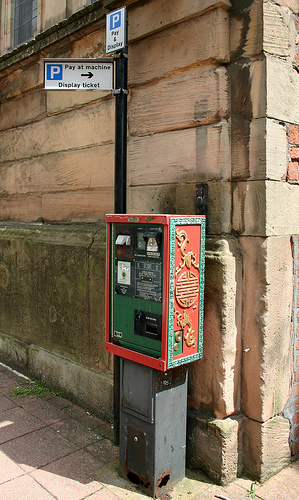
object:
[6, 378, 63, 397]
weeds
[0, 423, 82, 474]
cement tile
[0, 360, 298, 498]
ground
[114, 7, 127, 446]
pole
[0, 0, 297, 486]
building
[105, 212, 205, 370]
box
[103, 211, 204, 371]
machine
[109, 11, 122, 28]
p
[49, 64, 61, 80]
p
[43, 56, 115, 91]
sign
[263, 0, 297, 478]
wall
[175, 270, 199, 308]
asian decor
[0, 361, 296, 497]
sidewalk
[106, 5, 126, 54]
sign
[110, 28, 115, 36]
words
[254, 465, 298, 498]
cement tile